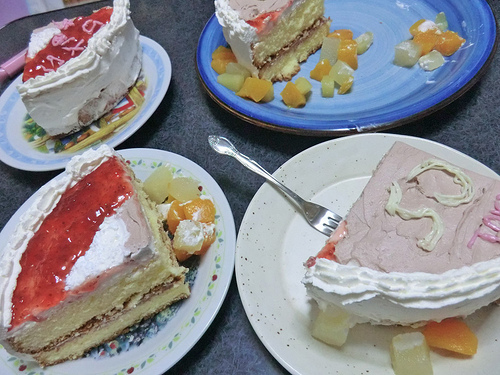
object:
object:
[0, 46, 26, 86]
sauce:
[8, 157, 134, 332]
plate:
[0, 147, 236, 375]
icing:
[333, 142, 500, 274]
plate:
[195, 0, 498, 137]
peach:
[319, 74, 337, 98]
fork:
[206, 134, 343, 238]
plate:
[234, 133, 500, 375]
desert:
[213, 0, 331, 83]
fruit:
[235, 75, 272, 104]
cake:
[0, 143, 192, 366]